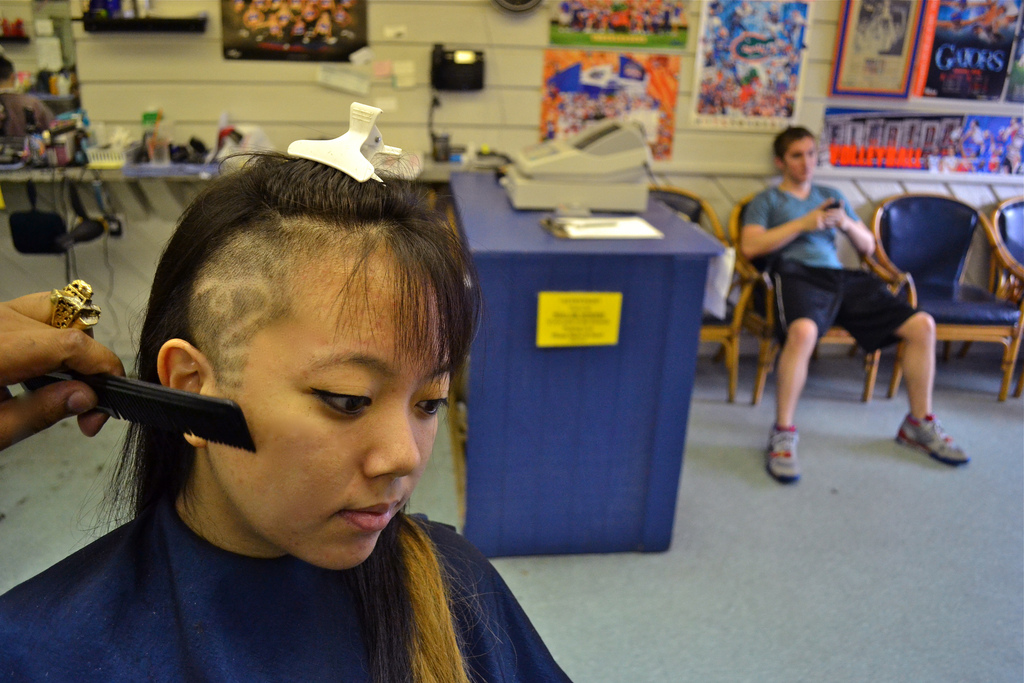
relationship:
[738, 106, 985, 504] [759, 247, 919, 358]
boy wearing shorts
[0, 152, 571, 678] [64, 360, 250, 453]
person holding comb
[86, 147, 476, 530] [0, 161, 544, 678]
hair of person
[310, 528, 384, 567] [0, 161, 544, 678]
chin of person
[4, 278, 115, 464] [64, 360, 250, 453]
person holding comb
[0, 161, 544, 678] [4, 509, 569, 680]
person wearing cloth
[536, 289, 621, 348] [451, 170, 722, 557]
sign on counter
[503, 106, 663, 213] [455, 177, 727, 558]
cash register on counter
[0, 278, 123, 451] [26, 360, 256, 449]
person holding comb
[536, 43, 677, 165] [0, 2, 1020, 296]
poster on wall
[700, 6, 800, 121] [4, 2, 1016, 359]
poster on wall